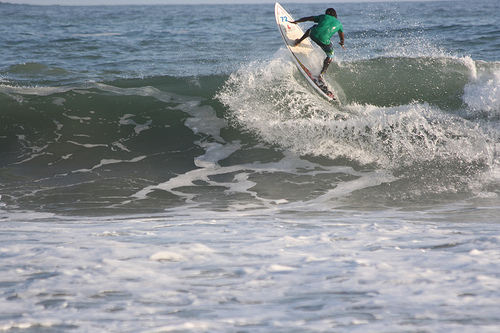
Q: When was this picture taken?
A: Daytime.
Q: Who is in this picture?
A: A surfer.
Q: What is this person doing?
A: Surfing.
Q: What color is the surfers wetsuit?
A: Green.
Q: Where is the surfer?
A: In the ocean.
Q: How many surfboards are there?
A: One.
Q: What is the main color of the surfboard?
A: White.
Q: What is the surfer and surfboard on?
A: A wave.